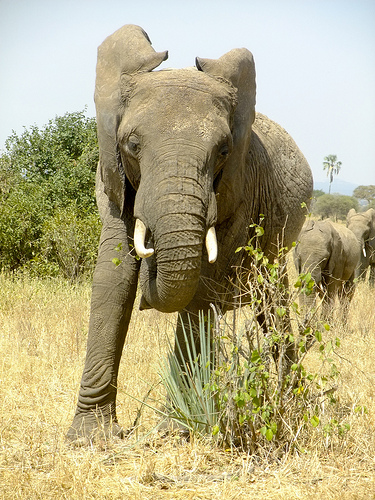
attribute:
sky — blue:
[3, 1, 350, 189]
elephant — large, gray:
[51, 14, 312, 470]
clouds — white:
[17, 20, 77, 111]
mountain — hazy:
[287, 152, 371, 210]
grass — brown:
[162, 399, 339, 484]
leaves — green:
[0, 103, 103, 280]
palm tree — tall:
[321, 152, 341, 197]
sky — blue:
[0, 0, 374, 194]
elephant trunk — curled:
[125, 172, 225, 316]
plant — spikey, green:
[13, 131, 88, 238]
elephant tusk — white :
[124, 195, 232, 268]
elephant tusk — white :
[293, 273, 329, 293]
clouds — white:
[133, 12, 355, 93]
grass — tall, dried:
[1, 273, 372, 499]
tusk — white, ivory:
[204, 222, 219, 262]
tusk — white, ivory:
[131, 219, 155, 258]